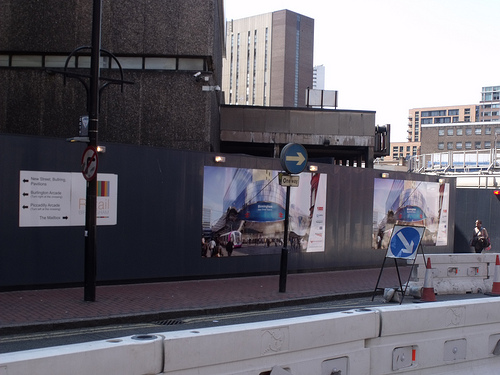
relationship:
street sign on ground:
[387, 224, 432, 261] [221, 269, 471, 308]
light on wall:
[215, 150, 227, 164] [3, 132, 498, 288]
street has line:
[5, 287, 380, 356] [4, 294, 378, 344]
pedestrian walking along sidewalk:
[467, 219, 491, 251] [13, 263, 457, 328]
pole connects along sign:
[270, 184, 295, 296] [266, 142, 313, 194]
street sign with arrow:
[387, 224, 432, 261] [397, 229, 416, 254]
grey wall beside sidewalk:
[0, 132, 477, 289] [0, 267, 412, 327]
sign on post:
[80, 142, 102, 179] [78, 2, 105, 303]